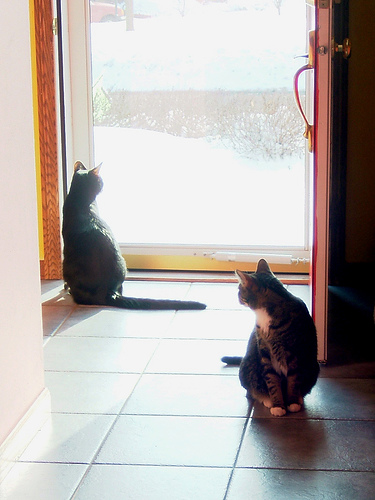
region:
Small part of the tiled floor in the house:
[126, 412, 191, 450]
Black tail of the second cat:
[115, 294, 213, 312]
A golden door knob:
[338, 38, 354, 60]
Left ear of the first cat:
[231, 266, 254, 284]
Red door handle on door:
[292, 66, 309, 126]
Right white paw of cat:
[269, 408, 284, 417]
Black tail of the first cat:
[221, 353, 237, 366]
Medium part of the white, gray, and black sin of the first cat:
[259, 315, 283, 347]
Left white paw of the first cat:
[286, 402, 300, 412]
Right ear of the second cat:
[91, 163, 103, 173]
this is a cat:
[57, 162, 126, 305]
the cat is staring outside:
[63, 153, 125, 304]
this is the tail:
[117, 285, 209, 310]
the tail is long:
[114, 287, 207, 312]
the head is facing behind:
[233, 262, 286, 318]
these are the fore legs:
[269, 355, 301, 415]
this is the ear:
[233, 264, 245, 284]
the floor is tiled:
[85, 376, 199, 488]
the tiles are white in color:
[57, 363, 202, 497]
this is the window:
[141, 104, 288, 218]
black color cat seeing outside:
[52, 154, 154, 314]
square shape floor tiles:
[111, 340, 197, 474]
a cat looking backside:
[224, 259, 324, 422]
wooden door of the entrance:
[304, 10, 336, 390]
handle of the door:
[294, 58, 315, 148]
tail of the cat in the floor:
[119, 291, 206, 313]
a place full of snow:
[121, 112, 275, 207]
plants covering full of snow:
[216, 98, 293, 166]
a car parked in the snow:
[93, 0, 129, 32]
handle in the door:
[338, 37, 350, 61]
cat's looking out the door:
[59, 152, 331, 463]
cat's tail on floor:
[98, 289, 212, 322]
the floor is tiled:
[40, 272, 373, 497]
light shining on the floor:
[40, 273, 349, 497]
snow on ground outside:
[92, 118, 311, 253]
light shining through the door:
[55, 4, 331, 272]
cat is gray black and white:
[218, 257, 328, 445]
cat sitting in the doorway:
[46, 103, 164, 355]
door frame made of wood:
[26, 0, 82, 320]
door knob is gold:
[326, 30, 367, 74]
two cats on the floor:
[56, 149, 328, 428]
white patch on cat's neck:
[243, 303, 272, 330]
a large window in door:
[81, 3, 309, 260]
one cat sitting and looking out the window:
[51, 151, 211, 316]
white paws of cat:
[260, 396, 311, 415]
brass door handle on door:
[281, 26, 336, 161]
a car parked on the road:
[79, 5, 126, 19]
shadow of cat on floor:
[41, 285, 101, 338]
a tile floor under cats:
[40, 273, 344, 498]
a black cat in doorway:
[50, 157, 208, 304]